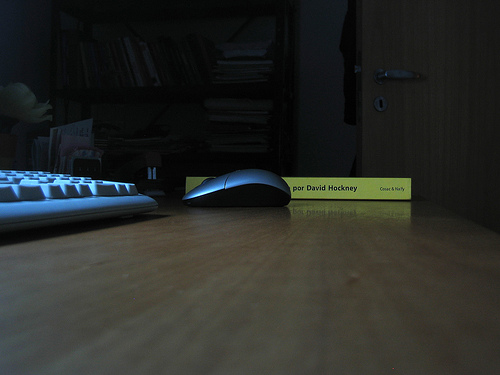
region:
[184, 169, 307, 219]
Black and gray computer mouse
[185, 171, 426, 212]
Yellow directory or book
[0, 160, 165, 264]
Key pad for computer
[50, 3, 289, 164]
Shelf with books and documents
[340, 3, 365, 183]
Door with looks like jacket hanging up on it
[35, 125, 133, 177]
Desk holder with mail and/or recipts in it.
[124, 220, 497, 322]
Brown table or desk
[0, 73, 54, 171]
Holder with white flower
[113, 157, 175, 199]
Large brown stapler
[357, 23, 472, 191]
Door to office or room used as office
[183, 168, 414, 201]
a book by David Hockney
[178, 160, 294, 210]
a silver computer mouse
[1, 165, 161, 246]
a white keyboard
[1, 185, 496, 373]
a laminated wood pattern computer desk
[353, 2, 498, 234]
a wooden door with a handle and keyhole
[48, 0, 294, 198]
a black shelf full of books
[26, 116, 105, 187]
an assortment of papers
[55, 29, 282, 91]
a row of books on a shelf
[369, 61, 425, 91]
the handle of a door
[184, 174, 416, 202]
the spine of a yellow book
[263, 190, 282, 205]
lower part of a mouse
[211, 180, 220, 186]
clicking part of a mouse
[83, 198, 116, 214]
edge of a key board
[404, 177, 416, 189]
bottom of a book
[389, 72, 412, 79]
part of a door knob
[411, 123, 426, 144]
part of a door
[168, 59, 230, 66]
books in a shelf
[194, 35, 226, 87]
part of a shelf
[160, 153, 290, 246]
mouse on the table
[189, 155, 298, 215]
silver mouse on the table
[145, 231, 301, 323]
brown table in a room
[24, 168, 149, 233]
keyboard in the room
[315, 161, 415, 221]
yellow book next to mouse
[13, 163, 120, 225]
white and blue keyboard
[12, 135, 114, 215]
keys on the keyboard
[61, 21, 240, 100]
books on the bookshelf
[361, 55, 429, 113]
handle to the door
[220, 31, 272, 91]
books stacked on each other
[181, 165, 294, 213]
Computer mouse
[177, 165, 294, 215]
Wireless computer mouse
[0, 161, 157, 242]
White keyboard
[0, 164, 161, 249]
White keyboard side view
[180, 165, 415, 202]
Book laying on wooden desk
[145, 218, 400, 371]
Desk made of brown wood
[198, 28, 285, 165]
Books on bookcase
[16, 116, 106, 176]
Papers standing up on desk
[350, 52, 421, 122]
Silver door handle and lock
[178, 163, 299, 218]
Silver and black wireless computer mouse